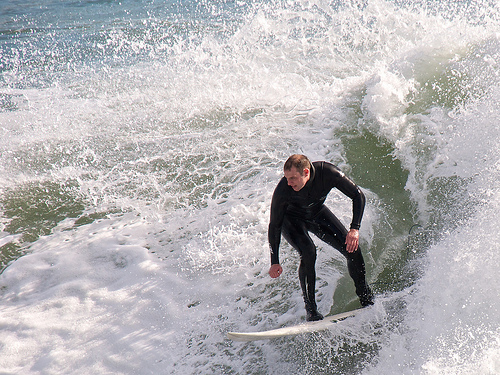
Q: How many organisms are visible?
A: One.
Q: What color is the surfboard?
A: White.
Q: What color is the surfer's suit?
A: Black.